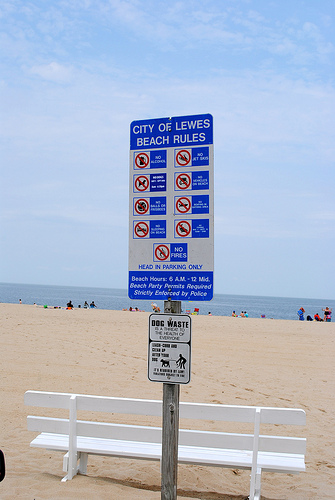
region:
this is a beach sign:
[170, 197, 206, 282]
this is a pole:
[133, 392, 202, 458]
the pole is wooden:
[149, 432, 186, 476]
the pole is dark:
[143, 442, 177, 487]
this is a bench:
[65, 394, 101, 434]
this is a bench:
[107, 428, 131, 453]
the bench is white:
[116, 440, 126, 450]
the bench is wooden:
[88, 438, 119, 476]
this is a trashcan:
[0, 466, 19, 474]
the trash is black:
[1, 472, 7, 473]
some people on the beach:
[207, 304, 331, 324]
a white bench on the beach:
[24, 391, 306, 498]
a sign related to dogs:
[148, 312, 191, 380]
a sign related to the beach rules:
[128, 116, 213, 299]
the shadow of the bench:
[105, 473, 248, 498]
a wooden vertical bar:
[161, 384, 177, 496]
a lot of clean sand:
[217, 332, 328, 395]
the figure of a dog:
[160, 357, 171, 366]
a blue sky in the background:
[10, 148, 106, 242]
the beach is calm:
[3, 283, 95, 298]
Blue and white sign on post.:
[130, 110, 208, 412]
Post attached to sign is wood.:
[155, 379, 176, 491]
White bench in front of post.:
[59, 382, 248, 490]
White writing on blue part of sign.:
[128, 121, 228, 155]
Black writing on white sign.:
[144, 311, 222, 402]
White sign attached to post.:
[139, 307, 192, 386]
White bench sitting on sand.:
[24, 384, 265, 495]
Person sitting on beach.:
[58, 295, 82, 320]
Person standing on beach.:
[321, 301, 332, 318]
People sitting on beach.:
[229, 303, 267, 336]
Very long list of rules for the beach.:
[120, 100, 220, 305]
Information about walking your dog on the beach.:
[139, 307, 198, 393]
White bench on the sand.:
[22, 382, 306, 496]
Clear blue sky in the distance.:
[233, 252, 318, 294]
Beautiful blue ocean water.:
[237, 303, 293, 311]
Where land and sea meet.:
[238, 278, 311, 306]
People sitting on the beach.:
[18, 298, 110, 312]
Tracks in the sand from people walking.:
[201, 372, 288, 395]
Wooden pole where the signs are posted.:
[145, 386, 188, 498]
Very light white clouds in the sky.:
[28, 93, 101, 198]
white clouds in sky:
[4, 2, 332, 281]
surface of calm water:
[0, 285, 331, 318]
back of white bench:
[23, 389, 307, 496]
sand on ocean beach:
[2, 304, 332, 495]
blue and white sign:
[129, 113, 214, 297]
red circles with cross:
[133, 148, 191, 261]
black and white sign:
[147, 313, 190, 384]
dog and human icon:
[157, 353, 186, 368]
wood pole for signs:
[160, 300, 181, 498]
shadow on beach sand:
[82, 471, 258, 498]